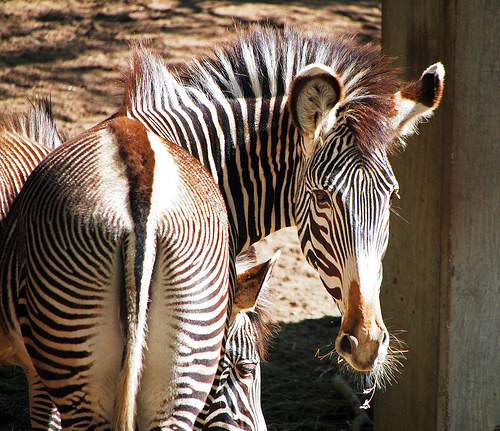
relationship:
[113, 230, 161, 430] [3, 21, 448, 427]
tail of a zebra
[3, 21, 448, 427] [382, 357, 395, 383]
zebra has whiskers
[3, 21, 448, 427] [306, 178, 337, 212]
zebra has an eye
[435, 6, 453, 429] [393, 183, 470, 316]
post in enclosure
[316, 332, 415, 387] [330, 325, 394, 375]
whiskers are under nose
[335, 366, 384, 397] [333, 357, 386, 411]
twig in mouth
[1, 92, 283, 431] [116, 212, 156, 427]
zebra has tail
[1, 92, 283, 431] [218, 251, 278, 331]
zebra has ear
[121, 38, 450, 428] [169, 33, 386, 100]
zebra has mane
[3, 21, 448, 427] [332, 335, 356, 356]
zebra has nostril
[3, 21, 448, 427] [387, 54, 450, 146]
zebra has ear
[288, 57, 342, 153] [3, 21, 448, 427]
ear of a zebra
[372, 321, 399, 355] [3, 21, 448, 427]
nostril of a zebra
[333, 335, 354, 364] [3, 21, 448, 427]
nostril of a zebra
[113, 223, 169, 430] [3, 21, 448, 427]
tail of a zebra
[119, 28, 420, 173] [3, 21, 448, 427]
mane of a zebra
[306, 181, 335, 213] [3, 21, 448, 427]
eye of a zebra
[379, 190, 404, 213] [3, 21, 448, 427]
eye of a zebra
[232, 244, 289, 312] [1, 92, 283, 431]
ear of a zebra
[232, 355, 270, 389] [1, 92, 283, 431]
eye of a zebra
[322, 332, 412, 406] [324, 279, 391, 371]
whiskers on snout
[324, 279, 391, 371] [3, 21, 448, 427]
snout of zebra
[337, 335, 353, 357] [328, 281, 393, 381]
nostril on nose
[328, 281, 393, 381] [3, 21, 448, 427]
nose of zebra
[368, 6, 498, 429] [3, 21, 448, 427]
post next to a zebra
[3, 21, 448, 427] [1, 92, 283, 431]
zebra standing next to zebra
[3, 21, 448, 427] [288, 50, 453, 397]
zebra turning her head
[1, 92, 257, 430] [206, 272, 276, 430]
zebra lowering her head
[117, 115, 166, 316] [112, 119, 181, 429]
stripe on tail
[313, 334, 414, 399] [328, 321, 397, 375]
whiskers on mouth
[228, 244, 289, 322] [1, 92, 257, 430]
ear on zebra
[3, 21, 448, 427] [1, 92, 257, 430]
zebra standing next to zebra